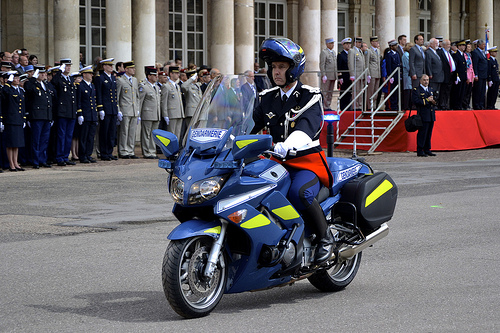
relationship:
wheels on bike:
[161, 234, 230, 321] [138, 59, 401, 314]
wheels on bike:
[151, 234, 231, 321] [138, 59, 401, 314]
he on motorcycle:
[245, 36, 338, 265] [131, 69, 402, 325]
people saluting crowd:
[323, 37, 484, 152] [9, 57, 179, 152]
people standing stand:
[342, 33, 484, 93] [334, 105, 484, 155]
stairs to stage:
[325, 67, 407, 152] [332, 109, 484, 150]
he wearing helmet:
[245, 36, 338, 265] [257, 28, 308, 72]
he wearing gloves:
[245, 36, 338, 265] [273, 126, 308, 155]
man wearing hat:
[335, 32, 361, 105] [336, 35, 354, 46]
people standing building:
[2, 44, 207, 164] [3, 6, 483, 126]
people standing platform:
[329, 29, 481, 101] [335, 102, 484, 153]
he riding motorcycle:
[245, 36, 338, 265] [131, 69, 402, 325]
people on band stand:
[328, 28, 482, 108] [323, 110, 484, 148]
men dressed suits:
[115, 58, 212, 157] [119, 73, 143, 150]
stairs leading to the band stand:
[325, 67, 407, 152] [323, 110, 484, 148]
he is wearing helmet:
[245, 36, 338, 265] [258, 31, 307, 87]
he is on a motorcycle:
[247, 45, 341, 268] [150, 70, 400, 318]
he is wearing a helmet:
[245, 36, 338, 265] [257, 31, 310, 81]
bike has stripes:
[152, 74, 400, 321] [198, 175, 397, 235]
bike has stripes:
[152, 74, 400, 321] [235, 134, 264, 148]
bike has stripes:
[152, 74, 400, 321] [153, 130, 171, 146]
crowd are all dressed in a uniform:
[0, 52, 221, 170] [6, 57, 219, 163]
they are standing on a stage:
[320, 33, 484, 109] [321, 104, 484, 152]